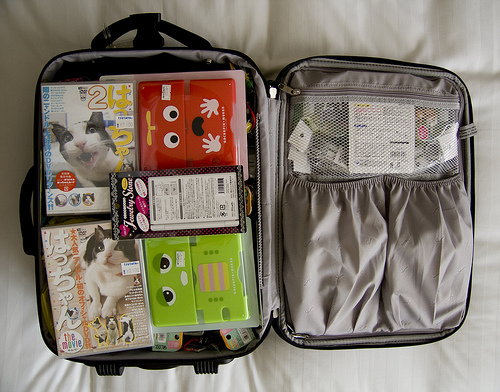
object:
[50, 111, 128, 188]
cat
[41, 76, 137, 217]
dvd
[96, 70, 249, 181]
case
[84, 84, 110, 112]
number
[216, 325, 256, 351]
toy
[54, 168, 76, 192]
tag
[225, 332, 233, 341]
hole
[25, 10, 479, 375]
suitcase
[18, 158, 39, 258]
handle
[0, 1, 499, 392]
sheet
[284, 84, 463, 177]
compartment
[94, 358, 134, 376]
wheels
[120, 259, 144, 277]
sticker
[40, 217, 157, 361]
dvd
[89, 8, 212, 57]
handle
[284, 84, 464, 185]
mesh net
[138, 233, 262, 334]
case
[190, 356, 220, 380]
wheels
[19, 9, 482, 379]
luggage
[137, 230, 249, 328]
disk holder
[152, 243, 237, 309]
silly face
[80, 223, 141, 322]
cat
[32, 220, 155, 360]
magazine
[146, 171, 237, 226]
cards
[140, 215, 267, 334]
pack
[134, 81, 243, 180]
holder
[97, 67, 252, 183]
pack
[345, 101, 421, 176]
items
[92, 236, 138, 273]
face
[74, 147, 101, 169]
mouth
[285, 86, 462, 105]
zipper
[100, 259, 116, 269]
mouth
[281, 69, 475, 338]
lining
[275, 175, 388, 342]
pocket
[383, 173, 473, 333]
pocket